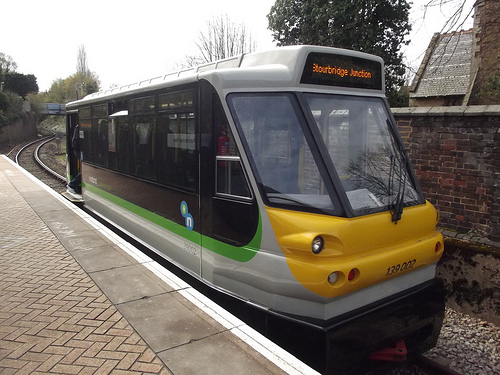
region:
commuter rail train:
[59, 42, 452, 354]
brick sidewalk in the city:
[3, 150, 313, 372]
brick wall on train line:
[391, 104, 494, 244]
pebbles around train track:
[449, 312, 492, 370]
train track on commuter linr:
[17, 130, 70, 185]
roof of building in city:
[404, 26, 499, 105]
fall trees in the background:
[2, 43, 95, 96]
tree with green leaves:
[263, 0, 412, 104]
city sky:
[2, 8, 278, 88]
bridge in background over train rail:
[36, 98, 71, 115]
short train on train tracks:
[53, 39, 464, 370]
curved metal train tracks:
[11, 123, 71, 194]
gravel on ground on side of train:
[431, 305, 499, 371]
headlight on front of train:
[291, 228, 336, 259]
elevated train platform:
[1, 154, 320, 371]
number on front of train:
[372, 253, 432, 280]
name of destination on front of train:
[301, 52, 382, 85]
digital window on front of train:
[294, 48, 384, 93]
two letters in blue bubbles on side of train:
[168, 194, 208, 238]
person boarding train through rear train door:
[62, 106, 87, 202]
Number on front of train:
[381, 259, 421, 279]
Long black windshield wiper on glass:
[395, 147, 412, 223]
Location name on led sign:
[306, 58, 376, 83]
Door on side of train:
[63, 107, 84, 197]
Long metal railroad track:
[16, 135, 70, 192]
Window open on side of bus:
[108, 98, 132, 118]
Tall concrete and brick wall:
[388, 108, 498, 324]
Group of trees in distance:
[1, 45, 103, 112]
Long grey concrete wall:
[1, 108, 39, 150]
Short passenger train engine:
[65, 46, 445, 366]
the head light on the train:
[296, 234, 332, 251]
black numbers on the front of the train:
[378, 256, 427, 281]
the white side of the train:
[253, 269, 292, 301]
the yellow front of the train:
[370, 235, 393, 252]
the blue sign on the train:
[175, 202, 201, 231]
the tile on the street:
[40, 278, 75, 314]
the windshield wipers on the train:
[378, 152, 410, 225]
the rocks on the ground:
[470, 324, 488, 351]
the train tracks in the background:
[20, 144, 45, 164]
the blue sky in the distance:
[87, 2, 138, 40]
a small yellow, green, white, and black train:
[59, 42, 444, 351]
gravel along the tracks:
[437, 297, 498, 371]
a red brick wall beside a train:
[291, 113, 497, 235]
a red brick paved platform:
[0, 172, 166, 372]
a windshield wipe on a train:
[374, 114, 409, 221]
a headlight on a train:
[308, 233, 329, 259]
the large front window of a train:
[298, 90, 427, 214]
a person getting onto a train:
[62, 108, 84, 194]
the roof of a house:
[417, 29, 472, 99]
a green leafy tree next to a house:
[269, 0, 411, 100]